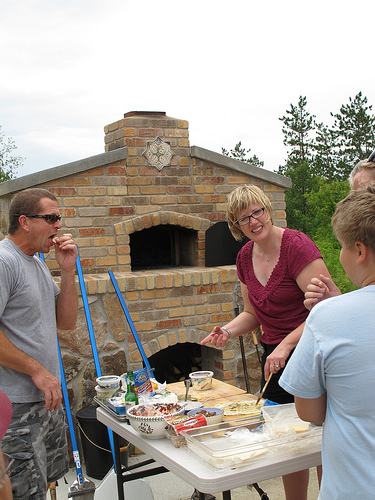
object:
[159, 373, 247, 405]
boards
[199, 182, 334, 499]
woman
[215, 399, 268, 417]
pizza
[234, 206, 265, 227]
glasses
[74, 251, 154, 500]
tool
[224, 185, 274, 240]
hair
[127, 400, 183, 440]
bowl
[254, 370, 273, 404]
brush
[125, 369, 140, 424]
beer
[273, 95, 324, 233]
tree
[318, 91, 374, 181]
tree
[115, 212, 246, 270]
train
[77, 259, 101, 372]
peel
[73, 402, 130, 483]
tub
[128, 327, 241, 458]
fireplace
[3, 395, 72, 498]
cargo pants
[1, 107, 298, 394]
brick oven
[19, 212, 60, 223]
black sunglasses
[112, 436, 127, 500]
leg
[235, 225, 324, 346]
blouse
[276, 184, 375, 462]
boy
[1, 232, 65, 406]
shirt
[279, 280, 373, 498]
shirt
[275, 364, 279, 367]
wedding ring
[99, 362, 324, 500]
table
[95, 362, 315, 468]
food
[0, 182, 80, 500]
man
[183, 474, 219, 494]
edge